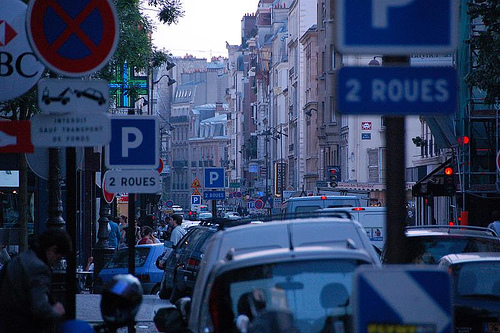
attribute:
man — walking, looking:
[11, 227, 70, 332]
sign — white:
[33, 112, 112, 143]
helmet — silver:
[102, 275, 138, 319]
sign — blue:
[108, 117, 158, 166]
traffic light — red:
[442, 162, 456, 198]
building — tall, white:
[286, 10, 305, 194]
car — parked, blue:
[110, 245, 166, 298]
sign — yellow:
[190, 177, 201, 190]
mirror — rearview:
[210, 249, 371, 331]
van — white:
[185, 224, 380, 331]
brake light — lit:
[353, 205, 365, 212]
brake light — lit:
[318, 196, 328, 204]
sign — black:
[106, 171, 159, 191]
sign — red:
[23, 3, 119, 79]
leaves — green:
[125, 19, 148, 70]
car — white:
[183, 218, 200, 226]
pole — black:
[127, 107, 135, 329]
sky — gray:
[138, 3, 263, 55]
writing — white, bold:
[120, 128, 142, 157]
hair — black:
[38, 229, 70, 258]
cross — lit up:
[110, 59, 149, 109]